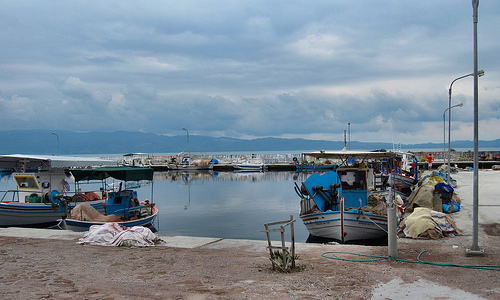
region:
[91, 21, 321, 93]
sky is blue and white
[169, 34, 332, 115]
thick clouds in sky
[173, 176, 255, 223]
water is blue and reflective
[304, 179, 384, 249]
white and blue boat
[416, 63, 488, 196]
tall and grey light poles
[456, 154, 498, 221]
sidewalk is light grey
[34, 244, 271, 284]
dirt and sand on ground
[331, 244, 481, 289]
green hose on ground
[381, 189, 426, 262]
grey pole on ground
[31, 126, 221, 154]
tall mountain in background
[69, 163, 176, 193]
green covering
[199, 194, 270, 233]
blue body of water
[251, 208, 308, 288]
sticks in the ground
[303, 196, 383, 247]
white boat with red and blue trim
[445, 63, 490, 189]
gray lamp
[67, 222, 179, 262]
white tarps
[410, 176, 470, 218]
heap of old rags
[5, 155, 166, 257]
boats docked at bay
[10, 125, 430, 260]
multiple boats docked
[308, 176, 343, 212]
metal contraption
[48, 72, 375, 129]
the sky is cloudy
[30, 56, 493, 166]
the sky is cloudy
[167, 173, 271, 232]
the water is calm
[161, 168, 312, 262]
the water is calm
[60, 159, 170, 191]
a green tarp covering a boat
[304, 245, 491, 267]
a green hose on the ground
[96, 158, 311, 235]
a body of water with several boats on it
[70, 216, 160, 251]
a tarp on the ground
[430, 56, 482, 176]
security lights on a tall poles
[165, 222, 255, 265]
a concrete walkway next to the water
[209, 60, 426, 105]
white clouds in a blue sky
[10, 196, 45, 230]
a white boat with red and blue stripe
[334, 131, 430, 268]
several boats tied to a dock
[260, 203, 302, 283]
a cage built around a plant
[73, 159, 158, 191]
Green covering on top of boat.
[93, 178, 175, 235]
White and blue boat in water.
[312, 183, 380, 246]
White boat docked in water.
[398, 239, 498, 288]
Green rope near pole.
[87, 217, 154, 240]
White material on sidewalk.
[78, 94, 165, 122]
White clouds in sky.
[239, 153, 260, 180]
Boat docked in water.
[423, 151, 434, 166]
Person wearing red shirt.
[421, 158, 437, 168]
Person wearing white shorts.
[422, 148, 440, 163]
Person has dark hair.